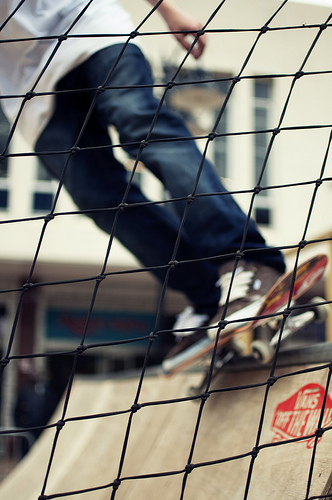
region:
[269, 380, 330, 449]
a red Vans emblem on the wood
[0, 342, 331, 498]
a skateboarding ramp for doing tricks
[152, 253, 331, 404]
a skateboard under the person's feet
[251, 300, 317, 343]
metal connecting the wheels to the skateboard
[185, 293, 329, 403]
gray colored wheels on the skateboard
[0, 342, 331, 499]
a wooden skateboard ramp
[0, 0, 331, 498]
a black fence made of rope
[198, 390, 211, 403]
a knot in the middle of the fence crossing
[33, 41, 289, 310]
a pair of blue jeans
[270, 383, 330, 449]
red and white skateboard-associated logo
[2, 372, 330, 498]
well used concrete skateboard ramp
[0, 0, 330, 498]
netting/fencing around skateboarding area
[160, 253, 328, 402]
red and multicolor skateboard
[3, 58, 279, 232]
windows in a nearby building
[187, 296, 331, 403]
wheels on the skateboard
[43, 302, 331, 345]
blurry blue and red sign in background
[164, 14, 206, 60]
skateboarder's hand helps to balance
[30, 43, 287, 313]
skateboarder wearing blue jeans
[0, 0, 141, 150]
skateboarder wearing white shirt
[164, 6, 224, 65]
the hands of a man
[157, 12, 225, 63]
the fingers of a man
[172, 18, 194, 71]
the thumb of a man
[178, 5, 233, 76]
the fingers of a man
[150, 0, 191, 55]
the wrist of a man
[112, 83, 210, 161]
the knee of a man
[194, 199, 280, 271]
the ankle of a man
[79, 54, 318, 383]
the legs of a man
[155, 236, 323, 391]
the feet of a man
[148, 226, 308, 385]
a man wearing shoes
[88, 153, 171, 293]
leg of a person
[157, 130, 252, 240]
leg of a person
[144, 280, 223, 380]
feet of a person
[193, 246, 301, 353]
feet of a person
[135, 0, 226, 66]
hand of a person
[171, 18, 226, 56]
finger of a person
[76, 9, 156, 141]
thigh of a person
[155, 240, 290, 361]
pair of sneaker of a person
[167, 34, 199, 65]
thumb of a person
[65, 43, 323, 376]
person on a skateboard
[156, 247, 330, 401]
a colorful skateboard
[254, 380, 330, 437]
red logo on the wall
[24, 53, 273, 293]
man wearing blue jeans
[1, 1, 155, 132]
man wearing a white shirt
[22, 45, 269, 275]
man with blue jeans on the skate board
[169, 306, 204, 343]
white shoe laces in the shoe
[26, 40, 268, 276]
man wearing blue jeans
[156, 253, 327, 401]
A red and blue skateboard